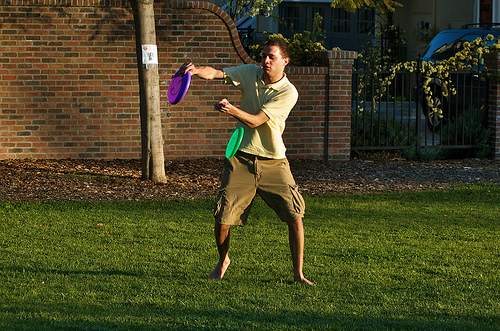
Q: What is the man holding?
A: A purple frisbee.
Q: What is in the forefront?
A: Green grass.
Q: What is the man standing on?
A: Green grass.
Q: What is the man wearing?
A: Brown shorts.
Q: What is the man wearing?
A: A beige shirt.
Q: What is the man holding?
A: A green frisbee.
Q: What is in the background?
A: A brick wall.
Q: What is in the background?
A: A tree.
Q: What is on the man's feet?
A: Nothing.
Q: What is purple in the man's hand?
A: Frisbee.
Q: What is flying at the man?
A: A green frisbee.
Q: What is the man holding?
A: A purple frisbee.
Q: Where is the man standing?
A: On the grass outside.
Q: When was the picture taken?
A: Daytime.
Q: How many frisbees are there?
A: Two.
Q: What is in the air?
A: A frisbee.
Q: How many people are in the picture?
A: One.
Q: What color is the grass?
A: Green.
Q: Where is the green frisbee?
A: In the air.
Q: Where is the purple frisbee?
A: In man's hand.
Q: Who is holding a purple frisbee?
A: A man.